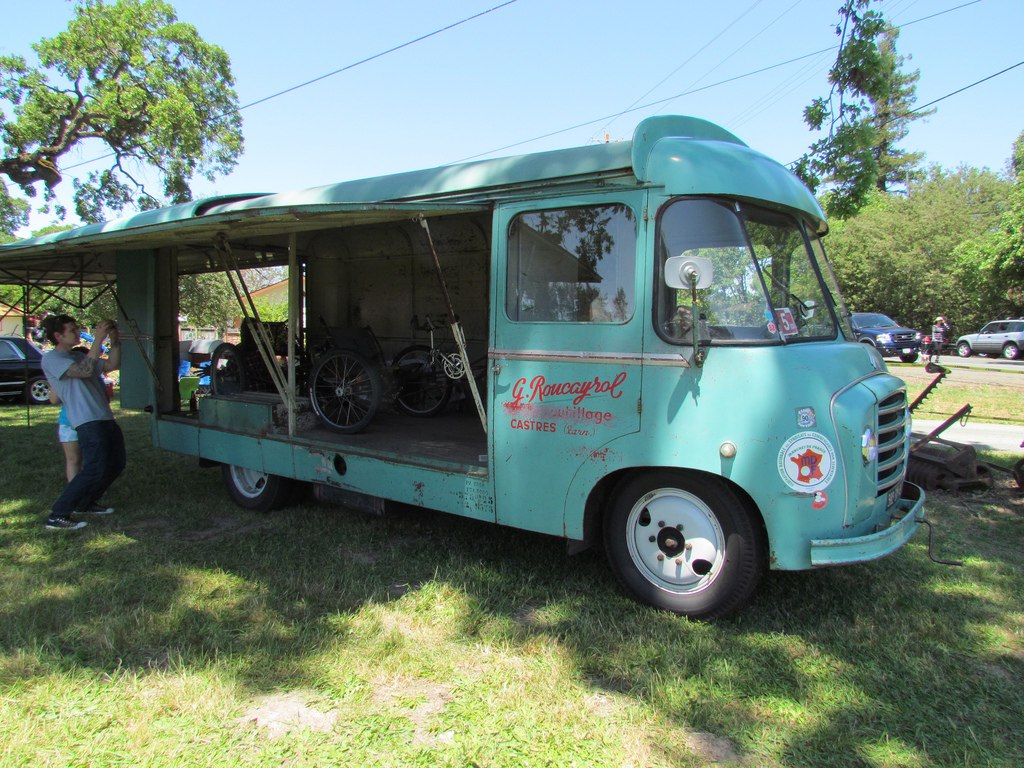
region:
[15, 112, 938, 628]
The bus is seafoam green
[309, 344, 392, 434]
The wheel is sitting in the back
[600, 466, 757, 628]
The wheel is black and white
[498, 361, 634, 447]
The writing is pink on the bus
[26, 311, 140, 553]
A man touching the bus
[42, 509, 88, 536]
A pair of brown and white shoes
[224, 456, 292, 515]
A wheel is black and white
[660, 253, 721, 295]
A silver side mirror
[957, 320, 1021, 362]
A silver and black suv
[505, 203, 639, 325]
A small rectangular window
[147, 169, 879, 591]
old light blue van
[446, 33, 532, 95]
white clouds in the blue sky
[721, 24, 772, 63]
white clouds in the blue sky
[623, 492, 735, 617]
front wheel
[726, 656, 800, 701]
shadow on the grass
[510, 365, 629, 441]
writing on the door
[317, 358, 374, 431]
a wheel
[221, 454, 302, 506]
back tire on the van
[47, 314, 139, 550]
a person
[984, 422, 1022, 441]
the street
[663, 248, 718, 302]
the side mirror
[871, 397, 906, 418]
slat on the blue truck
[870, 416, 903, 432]
slat on the blue truck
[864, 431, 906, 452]
slat on the blue truck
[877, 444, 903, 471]
slat on the blue truck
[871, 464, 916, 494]
slat on the blue truck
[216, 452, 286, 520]
wheel belongs to vehicle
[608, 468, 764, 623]
wheel belongs to vehicle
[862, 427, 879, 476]
headlight belongs to vehicle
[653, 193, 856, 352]
windshield belongs to vehicle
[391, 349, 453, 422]
wheel belongs to bicycle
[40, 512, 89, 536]
sneaker worn by human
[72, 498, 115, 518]
sneaker worn by human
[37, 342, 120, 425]
shirt worn by human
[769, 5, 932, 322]
tree behind vehicle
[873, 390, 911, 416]
slat on the grill on the blue truck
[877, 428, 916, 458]
slat on the grill on the blue truck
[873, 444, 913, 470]
slat on the grill on the blue truck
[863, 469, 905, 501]
slat on the grill on the blue truck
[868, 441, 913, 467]
slat on the grill on the blue truck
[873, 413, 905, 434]
slat on the grill on the blue truck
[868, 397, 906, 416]
slat on the grill on the blue truck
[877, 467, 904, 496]
slat on the grill on the blue truck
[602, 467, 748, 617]
the tire is black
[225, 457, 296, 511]
the tire is black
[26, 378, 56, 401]
the tire is black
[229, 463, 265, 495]
hub cap on tire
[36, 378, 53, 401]
hub cap on tire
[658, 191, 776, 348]
window of a bus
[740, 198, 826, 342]
window of a bus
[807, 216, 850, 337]
window of a bus